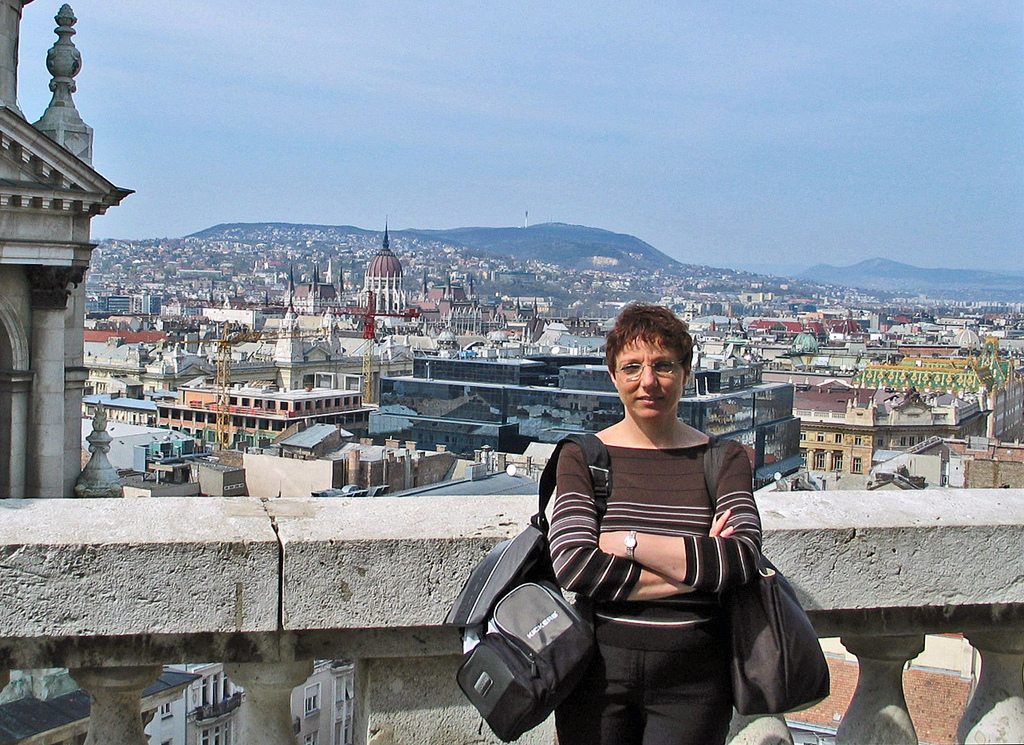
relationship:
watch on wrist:
[620, 527, 639, 553] [607, 515, 655, 572]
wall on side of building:
[368, 376, 520, 446] [356, 343, 806, 490]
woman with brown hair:
[550, 303, 765, 741] [598, 305, 694, 357]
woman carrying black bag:
[550, 303, 765, 741] [452, 507, 599, 739]